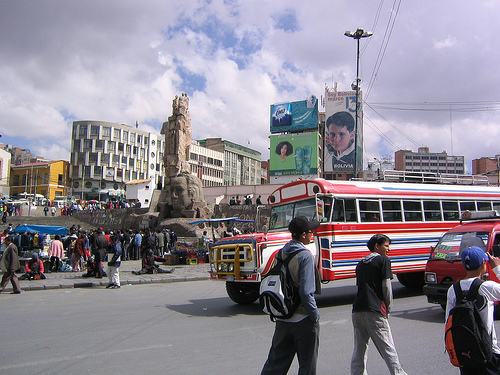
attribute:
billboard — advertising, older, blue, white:
[268, 95, 319, 134]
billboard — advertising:
[323, 90, 363, 173]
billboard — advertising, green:
[270, 132, 318, 176]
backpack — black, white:
[258, 248, 305, 321]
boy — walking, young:
[446, 246, 499, 374]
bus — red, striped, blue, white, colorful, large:
[209, 178, 499, 301]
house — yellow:
[11, 159, 69, 201]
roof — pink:
[10, 159, 71, 169]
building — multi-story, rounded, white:
[69, 120, 166, 207]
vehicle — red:
[422, 218, 500, 310]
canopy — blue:
[9, 224, 69, 237]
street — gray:
[1, 279, 499, 374]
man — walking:
[1, 235, 21, 294]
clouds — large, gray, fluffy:
[1, 1, 500, 175]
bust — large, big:
[157, 173, 226, 244]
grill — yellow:
[208, 243, 254, 282]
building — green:
[199, 136, 262, 186]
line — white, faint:
[1, 306, 442, 369]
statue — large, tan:
[158, 92, 194, 207]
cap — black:
[288, 216, 319, 234]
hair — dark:
[275, 141, 293, 155]